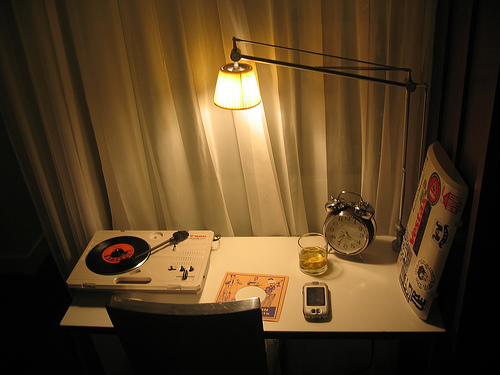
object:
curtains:
[1, 0, 499, 302]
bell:
[352, 201, 376, 222]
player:
[64, 230, 214, 295]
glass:
[296, 232, 329, 278]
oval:
[396, 140, 467, 321]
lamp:
[213, 36, 429, 253]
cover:
[213, 272, 292, 323]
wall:
[438, 0, 499, 330]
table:
[58, 236, 451, 374]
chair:
[105, 296, 283, 374]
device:
[301, 281, 333, 321]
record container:
[212, 271, 290, 322]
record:
[82, 235, 150, 278]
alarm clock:
[319, 189, 378, 263]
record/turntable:
[64, 224, 216, 296]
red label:
[99, 243, 135, 262]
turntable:
[64, 229, 215, 294]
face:
[327, 215, 364, 252]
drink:
[297, 247, 330, 273]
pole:
[242, 55, 404, 90]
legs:
[354, 253, 367, 262]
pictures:
[397, 142, 471, 324]